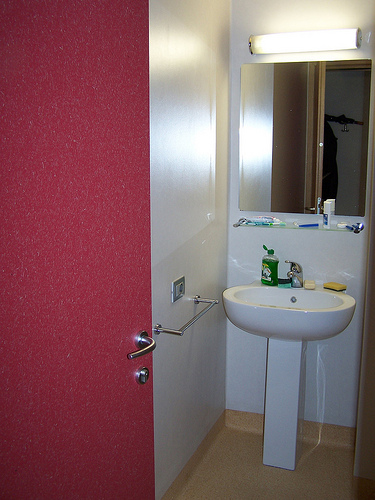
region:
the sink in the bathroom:
[213, 280, 357, 348]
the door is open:
[9, 18, 156, 496]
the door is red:
[4, 0, 155, 498]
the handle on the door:
[124, 336, 154, 360]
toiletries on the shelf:
[231, 210, 372, 231]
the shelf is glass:
[234, 221, 356, 232]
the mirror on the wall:
[244, 65, 365, 217]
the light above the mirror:
[240, 26, 365, 56]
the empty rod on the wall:
[153, 293, 220, 362]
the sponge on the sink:
[322, 277, 352, 295]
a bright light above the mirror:
[244, 20, 364, 59]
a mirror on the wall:
[232, 53, 374, 222]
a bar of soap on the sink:
[299, 277, 317, 292]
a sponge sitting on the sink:
[318, 278, 350, 294]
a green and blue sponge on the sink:
[274, 273, 296, 292]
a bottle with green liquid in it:
[255, 240, 282, 290]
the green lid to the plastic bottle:
[261, 244, 275, 256]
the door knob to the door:
[123, 326, 158, 363]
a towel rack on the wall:
[151, 288, 222, 342]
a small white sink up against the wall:
[210, 257, 357, 478]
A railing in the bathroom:
[157, 296, 215, 336]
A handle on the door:
[129, 333, 154, 356]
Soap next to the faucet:
[261, 245, 279, 285]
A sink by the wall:
[224, 260, 356, 473]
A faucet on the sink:
[284, 258, 304, 286]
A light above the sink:
[249, 29, 359, 55]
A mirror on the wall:
[237, 66, 368, 215]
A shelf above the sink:
[237, 214, 359, 230]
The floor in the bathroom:
[160, 423, 370, 498]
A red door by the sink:
[0, 1, 152, 499]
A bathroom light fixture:
[247, 28, 362, 53]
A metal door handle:
[126, 330, 156, 357]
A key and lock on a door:
[135, 366, 149, 382]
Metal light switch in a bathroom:
[170, 274, 186, 301]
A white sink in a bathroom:
[223, 280, 355, 468]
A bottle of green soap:
[259, 243, 278, 285]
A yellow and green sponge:
[322, 279, 346, 291]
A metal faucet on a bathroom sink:
[284, 259, 304, 286]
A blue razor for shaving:
[294, 221, 320, 228]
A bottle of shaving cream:
[321, 199, 331, 226]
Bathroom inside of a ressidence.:
[14, 15, 364, 481]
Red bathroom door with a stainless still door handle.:
[5, 2, 159, 498]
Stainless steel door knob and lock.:
[126, 323, 165, 395]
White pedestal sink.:
[220, 247, 356, 497]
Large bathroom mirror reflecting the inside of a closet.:
[225, 53, 371, 238]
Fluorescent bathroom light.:
[236, 23, 374, 64]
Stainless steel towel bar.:
[146, 287, 221, 366]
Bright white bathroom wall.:
[162, 14, 209, 467]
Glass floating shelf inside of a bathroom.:
[234, 198, 367, 247]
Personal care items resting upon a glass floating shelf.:
[227, 192, 372, 245]